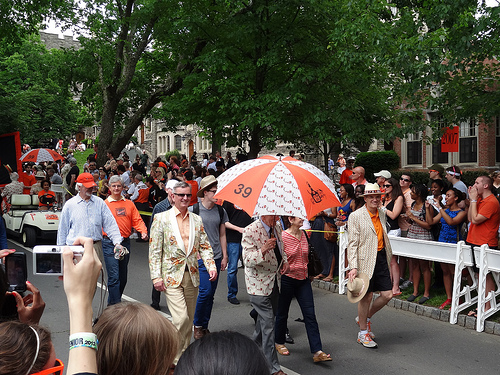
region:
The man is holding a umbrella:
[206, 157, 366, 229]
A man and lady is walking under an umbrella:
[231, 156, 336, 373]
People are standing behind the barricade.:
[394, 170, 496, 302]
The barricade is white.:
[403, 236, 491, 322]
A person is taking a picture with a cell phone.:
[15, 239, 102, 371]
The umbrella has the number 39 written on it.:
[228, 170, 256, 218]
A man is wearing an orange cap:
[53, 175, 127, 290]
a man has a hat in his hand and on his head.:
[347, 168, 417, 342]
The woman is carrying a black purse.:
[279, 224, 322, 296]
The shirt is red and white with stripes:
[278, 225, 316, 285]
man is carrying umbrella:
[214, 150, 346, 371]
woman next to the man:
[207, 150, 334, 368]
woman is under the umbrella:
[276, 213, 331, 364]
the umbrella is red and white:
[213, 150, 340, 220]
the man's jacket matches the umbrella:
[192, 152, 287, 373]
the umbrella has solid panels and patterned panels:
[211, 153, 341, 222]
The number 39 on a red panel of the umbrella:
[212, 160, 280, 225]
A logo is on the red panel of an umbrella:
[281, 158, 340, 223]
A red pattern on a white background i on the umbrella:
[252, 161, 304, 237]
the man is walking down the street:
[340, 182, 401, 353]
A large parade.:
[6, 106, 496, 366]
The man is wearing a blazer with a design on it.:
[147, 177, 218, 357]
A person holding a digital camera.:
[30, 240, 91, 276]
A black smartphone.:
[0, 245, 30, 292]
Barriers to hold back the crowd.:
[386, 225, 496, 327]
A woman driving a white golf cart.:
[10, 177, 70, 237]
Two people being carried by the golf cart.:
[2, 165, 43, 207]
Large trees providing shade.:
[0, 0, 385, 140]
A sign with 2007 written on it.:
[425, 115, 470, 170]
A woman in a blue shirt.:
[428, 185, 459, 310]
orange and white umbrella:
[210, 139, 345, 282]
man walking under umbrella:
[196, 157, 330, 373]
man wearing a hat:
[340, 169, 417, 353]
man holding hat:
[340, 165, 418, 357]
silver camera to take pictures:
[23, 234, 113, 304]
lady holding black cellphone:
[4, 241, 47, 311]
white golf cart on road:
[5, 172, 90, 264]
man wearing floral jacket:
[145, 168, 249, 342]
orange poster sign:
[430, 112, 484, 174]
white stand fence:
[385, 215, 498, 340]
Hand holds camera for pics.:
[31, 233, 101, 355]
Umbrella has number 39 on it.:
[217, 145, 344, 215]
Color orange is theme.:
[74, 155, 398, 263]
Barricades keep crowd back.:
[392, 228, 499, 328]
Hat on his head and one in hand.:
[347, 183, 400, 348]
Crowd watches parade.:
[337, 163, 498, 239]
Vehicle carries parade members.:
[10, 139, 70, 237]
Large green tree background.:
[59, 3, 176, 182]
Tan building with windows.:
[139, 114, 271, 156]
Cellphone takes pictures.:
[2, 243, 44, 322]